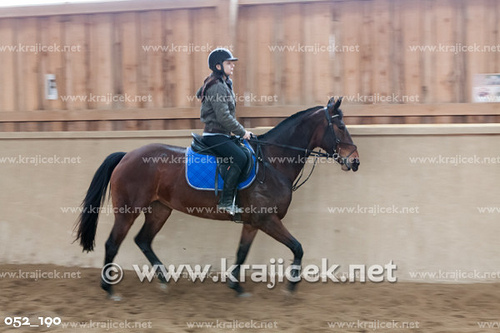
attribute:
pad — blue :
[182, 135, 264, 195]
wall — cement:
[0, 133, 491, 280]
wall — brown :
[2, 8, 497, 125]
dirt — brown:
[16, 263, 489, 328]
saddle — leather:
[190, 129, 242, 155]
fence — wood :
[0, 6, 495, 118]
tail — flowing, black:
[70, 144, 119, 254]